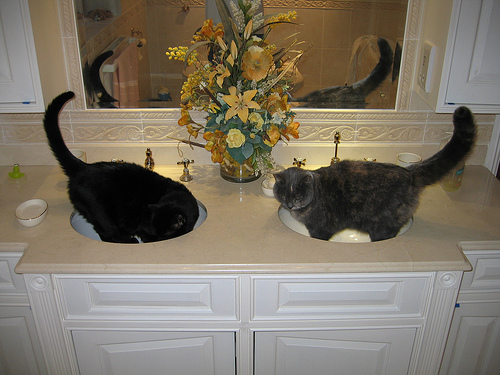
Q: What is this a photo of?
A: Two cats in a sink.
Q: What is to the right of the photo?
A: A gray cat in a sink.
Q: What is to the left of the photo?
A: A black cat in a sink.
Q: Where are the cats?
A: Inside two sinks on a counter.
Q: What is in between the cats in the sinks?
A: A vase with flowers.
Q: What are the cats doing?
A: Playing in the sinks.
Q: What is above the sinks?
A: A mirror.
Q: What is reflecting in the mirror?
A: Tails of the 2 cats.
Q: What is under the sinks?
A: Cabinets.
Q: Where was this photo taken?
A: Bathroom.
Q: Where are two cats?
A: In two sinks.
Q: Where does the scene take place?
A: In a bathroom.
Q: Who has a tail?
A: Both cats.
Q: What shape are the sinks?
A: Round.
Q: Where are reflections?
A: In the mirror.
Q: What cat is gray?
A: Cat on right.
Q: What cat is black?
A: Cat on left.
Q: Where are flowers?
A: On sink countertop.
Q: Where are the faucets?
A: Above the sinks.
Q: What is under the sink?
A: White cabinets.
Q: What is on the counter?
A: A yellow bouquet.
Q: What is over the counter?
A: A fancy trim.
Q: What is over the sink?
A: A mirror.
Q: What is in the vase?
A: Flowers.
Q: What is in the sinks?
A: Cats.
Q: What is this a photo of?
A: 2 cats in sinks.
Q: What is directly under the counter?
A: Drawers.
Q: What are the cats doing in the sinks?
A: Staying cool.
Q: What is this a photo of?
A: Cats in a sinks.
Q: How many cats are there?
A: Two.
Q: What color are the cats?
A: Black.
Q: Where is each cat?
A: In a sink.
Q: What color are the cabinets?
A: White.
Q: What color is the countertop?
A: Ivory.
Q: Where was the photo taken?
A: In the master bathroom.